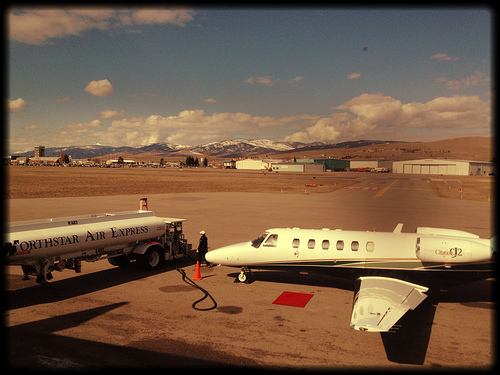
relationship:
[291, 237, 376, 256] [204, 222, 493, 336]
windows on plane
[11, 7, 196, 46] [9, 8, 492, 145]
clouds in sky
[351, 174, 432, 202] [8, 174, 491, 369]
lines on tarmac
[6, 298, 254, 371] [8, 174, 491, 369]
shadows on tarmac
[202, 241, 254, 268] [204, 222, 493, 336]
nose on plane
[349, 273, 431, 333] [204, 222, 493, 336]
wing on plane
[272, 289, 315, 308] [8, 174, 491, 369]
mat on tarmac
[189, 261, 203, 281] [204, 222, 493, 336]
cone near plane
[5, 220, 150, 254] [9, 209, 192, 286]
name on truck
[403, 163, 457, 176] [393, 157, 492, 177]
doors on building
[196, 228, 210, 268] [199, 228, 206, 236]
person wearing hat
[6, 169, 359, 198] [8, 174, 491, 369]
grass next to tarmac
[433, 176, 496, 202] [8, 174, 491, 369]
grass next to tarmac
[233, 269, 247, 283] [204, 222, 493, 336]
tire on plane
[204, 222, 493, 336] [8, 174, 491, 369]
plane on tarmac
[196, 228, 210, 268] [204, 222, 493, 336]
person in front of plane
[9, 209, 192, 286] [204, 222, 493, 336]
truck in front of plane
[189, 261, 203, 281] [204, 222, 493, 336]
cone in front of plane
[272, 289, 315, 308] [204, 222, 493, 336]
mat next to plane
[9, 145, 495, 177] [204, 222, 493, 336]
buildings behind plane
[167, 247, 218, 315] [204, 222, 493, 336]
gas hose next to plane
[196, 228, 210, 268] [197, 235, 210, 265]
person wearing clothing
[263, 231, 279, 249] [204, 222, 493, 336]
window on plane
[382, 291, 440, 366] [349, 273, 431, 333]
shadow of wing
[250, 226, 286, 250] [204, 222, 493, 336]
cockpit on plane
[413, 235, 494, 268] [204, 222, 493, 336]
engine on plane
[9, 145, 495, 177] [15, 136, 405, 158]
buildings in front of mountains